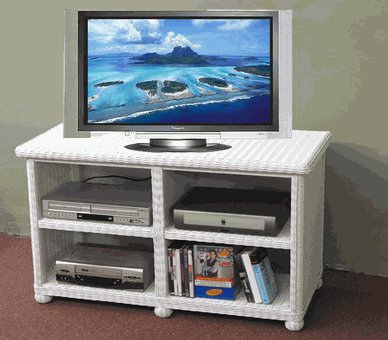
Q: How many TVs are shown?
A: One.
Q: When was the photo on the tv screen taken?
A: Daytime.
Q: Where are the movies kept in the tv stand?
A: Bottom right cubbie.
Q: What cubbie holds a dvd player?
A: Top Left.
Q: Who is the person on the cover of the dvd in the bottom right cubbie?
A: Jerry Seinfeld.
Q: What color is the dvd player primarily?
A: Silver.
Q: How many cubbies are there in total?
A: Four.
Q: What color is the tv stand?
A: White.